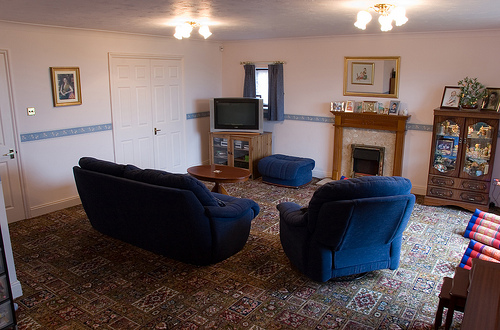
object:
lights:
[152, 0, 238, 41]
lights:
[339, 0, 421, 32]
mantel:
[329, 110, 411, 132]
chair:
[275, 175, 416, 282]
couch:
[72, 156, 260, 265]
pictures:
[329, 100, 401, 116]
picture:
[350, 61, 375, 85]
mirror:
[342, 55, 401, 99]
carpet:
[0, 175, 475, 330]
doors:
[107, 53, 156, 171]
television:
[209, 97, 265, 134]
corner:
[206, 39, 248, 173]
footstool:
[257, 154, 317, 188]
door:
[430, 118, 498, 178]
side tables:
[433, 276, 469, 330]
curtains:
[239, 60, 285, 121]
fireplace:
[329, 110, 412, 181]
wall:
[0, 21, 116, 226]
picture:
[51, 66, 82, 108]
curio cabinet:
[422, 106, 500, 213]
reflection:
[350, 61, 374, 85]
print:
[351, 61, 376, 85]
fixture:
[162, 0, 220, 40]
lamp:
[162, 12, 195, 40]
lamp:
[195, 15, 220, 39]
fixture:
[352, 0, 409, 33]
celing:
[0, 0, 500, 45]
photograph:
[56, 73, 76, 100]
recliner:
[275, 176, 415, 285]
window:
[255, 67, 269, 109]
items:
[329, 99, 408, 117]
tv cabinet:
[207, 132, 273, 181]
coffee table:
[187, 164, 251, 196]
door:
[148, 59, 189, 173]